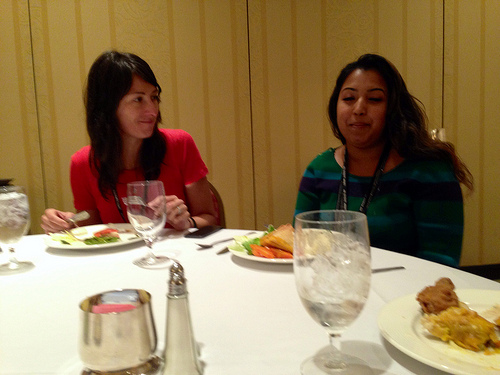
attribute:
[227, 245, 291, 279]
plate — white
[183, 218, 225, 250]
phone — black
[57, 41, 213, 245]
girl — smiling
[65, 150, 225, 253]
teeshirt — red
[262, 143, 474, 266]
blouse — striped, blue